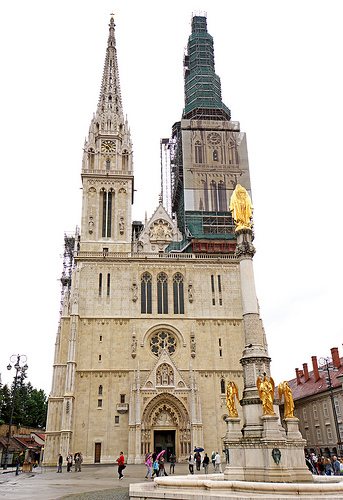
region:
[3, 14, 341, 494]
a historic town square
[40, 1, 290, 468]
the facade of a large, old building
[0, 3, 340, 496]
a city square centered around a historic church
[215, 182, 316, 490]
a grey fountain with gold figures on it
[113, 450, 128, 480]
a man wearing a red sweater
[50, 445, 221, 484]
a small crowd walking in front of the church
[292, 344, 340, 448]
a building with a red roof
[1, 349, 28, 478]
a tall light post with several lights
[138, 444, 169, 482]
a family holding colorful umbrellas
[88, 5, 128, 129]
a pointy spire on top of the church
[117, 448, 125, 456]
the head of a man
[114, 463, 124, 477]
the legs of a man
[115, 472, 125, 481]
the feet of a man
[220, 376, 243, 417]
a gold angel statue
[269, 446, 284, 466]
a fountain head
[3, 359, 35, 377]
street lights on the pole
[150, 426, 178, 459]
a pair of doors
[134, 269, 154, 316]
a window on the building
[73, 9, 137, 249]
a tower on the building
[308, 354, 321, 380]
a chimney on the building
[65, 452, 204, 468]
people in front the building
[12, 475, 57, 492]
the ground is wet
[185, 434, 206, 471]
person holding the umbrella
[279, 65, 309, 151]
the sky is gray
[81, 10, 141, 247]
the tower on the building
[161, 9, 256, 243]
the tower under construction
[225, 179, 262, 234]
the gold statue on the monument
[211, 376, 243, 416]
golden angel at the base of the monument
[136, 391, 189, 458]
the door way is arched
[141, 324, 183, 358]
circular window above the doorway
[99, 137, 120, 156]
a clock in the tower of a building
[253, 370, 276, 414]
the front of a golden angel statue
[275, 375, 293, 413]
the back of a golden angel statue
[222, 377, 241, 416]
the side of a golden angel statue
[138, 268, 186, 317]
three windows in a building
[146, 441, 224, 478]
people walking in a court yard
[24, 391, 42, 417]
the leaves of trees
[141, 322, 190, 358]
a round window in a building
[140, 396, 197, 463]
the arch way design of a doorway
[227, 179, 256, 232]
a golden statue at the top of a building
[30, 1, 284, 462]
A large cathedral building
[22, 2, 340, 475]
A cathedral under construction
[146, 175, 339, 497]
A fountain near a cathedral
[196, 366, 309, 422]
Gold statues on a fountain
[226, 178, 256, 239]
A gold statue on top of a fountain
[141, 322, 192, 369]
A rose window on a cathedral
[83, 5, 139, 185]
Spires on a cathedral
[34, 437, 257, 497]
People in front of a cathedral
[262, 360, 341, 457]
A building next to a cathedral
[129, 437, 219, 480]
People holding umbrellas